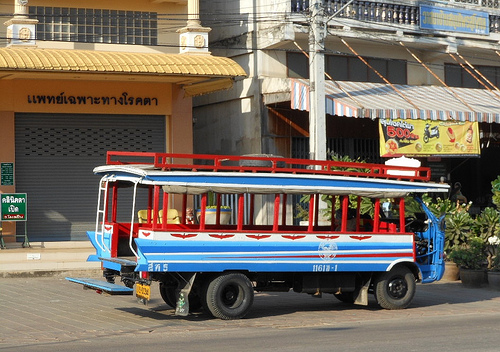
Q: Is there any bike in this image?
A: No, there are no bikes.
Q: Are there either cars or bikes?
A: No, there are no bikes or cars.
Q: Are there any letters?
A: Yes, there are letters.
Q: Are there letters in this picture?
A: Yes, there are letters.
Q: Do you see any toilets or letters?
A: Yes, there are letters.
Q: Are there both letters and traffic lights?
A: No, there are letters but no traffic lights.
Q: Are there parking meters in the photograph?
A: No, there are no parking meters.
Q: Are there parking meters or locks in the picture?
A: No, there are no parking meters or locks.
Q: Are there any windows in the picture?
A: Yes, there is a window.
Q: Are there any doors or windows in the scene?
A: Yes, there is a window.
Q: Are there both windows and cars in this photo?
A: No, there is a window but no cars.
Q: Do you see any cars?
A: No, there are no cars.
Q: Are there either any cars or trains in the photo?
A: No, there are no cars or trains.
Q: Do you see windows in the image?
A: Yes, there is a window.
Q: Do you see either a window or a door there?
A: Yes, there is a window.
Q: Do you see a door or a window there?
A: Yes, there is a window.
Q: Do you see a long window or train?
A: Yes, there is a long window.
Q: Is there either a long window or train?
A: Yes, there is a long window.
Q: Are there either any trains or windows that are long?
A: Yes, the window is long.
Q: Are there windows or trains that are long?
A: Yes, the window is long.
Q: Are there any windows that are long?
A: Yes, there is a long window.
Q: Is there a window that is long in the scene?
A: Yes, there is a long window.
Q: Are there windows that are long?
A: Yes, there is a window that is long.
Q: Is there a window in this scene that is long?
A: Yes, there is a window that is long.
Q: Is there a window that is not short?
A: Yes, there is a long window.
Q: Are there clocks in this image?
A: No, there are no clocks.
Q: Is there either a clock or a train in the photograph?
A: No, there are no clocks or trains.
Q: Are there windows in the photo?
A: Yes, there is a window.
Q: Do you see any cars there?
A: No, there are no cars.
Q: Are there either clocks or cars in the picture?
A: No, there are no cars or clocks.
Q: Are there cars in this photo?
A: No, there are no cars.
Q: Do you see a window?
A: Yes, there is a window.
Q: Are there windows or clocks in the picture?
A: Yes, there is a window.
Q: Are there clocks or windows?
A: Yes, there is a window.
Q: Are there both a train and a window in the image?
A: No, there is a window but no trains.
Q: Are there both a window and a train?
A: No, there is a window but no trains.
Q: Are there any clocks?
A: No, there are no clocks.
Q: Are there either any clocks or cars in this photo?
A: No, there are no clocks or cars.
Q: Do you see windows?
A: Yes, there is a window.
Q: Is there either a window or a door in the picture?
A: Yes, there is a window.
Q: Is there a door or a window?
A: Yes, there is a window.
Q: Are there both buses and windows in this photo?
A: Yes, there are both a window and a bus.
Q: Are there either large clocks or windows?
A: Yes, there is a large window.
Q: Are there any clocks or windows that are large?
A: Yes, the window is large.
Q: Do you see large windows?
A: Yes, there is a large window.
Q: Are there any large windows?
A: Yes, there is a large window.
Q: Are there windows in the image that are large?
A: Yes, there is a window that is large.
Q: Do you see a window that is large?
A: Yes, there is a window that is large.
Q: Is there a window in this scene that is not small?
A: Yes, there is a large window.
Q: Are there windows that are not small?
A: Yes, there is a large window.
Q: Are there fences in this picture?
A: No, there are no fences.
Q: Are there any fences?
A: No, there are no fences.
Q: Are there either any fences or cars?
A: No, there are no fences or cars.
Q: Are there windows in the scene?
A: Yes, there is a window.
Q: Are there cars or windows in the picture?
A: Yes, there is a window.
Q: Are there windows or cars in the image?
A: Yes, there is a window.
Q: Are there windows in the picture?
A: Yes, there is a window.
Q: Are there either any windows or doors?
A: Yes, there is a window.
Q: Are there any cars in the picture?
A: No, there are no cars.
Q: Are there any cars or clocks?
A: No, there are no cars or clocks.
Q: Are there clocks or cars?
A: No, there are no cars or clocks.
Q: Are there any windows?
A: Yes, there is a window.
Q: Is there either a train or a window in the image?
A: Yes, there is a window.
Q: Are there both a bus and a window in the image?
A: Yes, there are both a window and a bus.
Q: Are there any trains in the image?
A: No, there are no trains.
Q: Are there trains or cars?
A: No, there are no trains or cars.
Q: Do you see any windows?
A: Yes, there is a window.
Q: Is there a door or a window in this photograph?
A: Yes, there is a window.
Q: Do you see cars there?
A: No, there are no cars.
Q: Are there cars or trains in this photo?
A: No, there are no cars or trains.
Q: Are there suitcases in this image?
A: No, there are no suitcases.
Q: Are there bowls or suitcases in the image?
A: No, there are no suitcases or bowls.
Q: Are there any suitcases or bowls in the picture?
A: No, there are no suitcases or bowls.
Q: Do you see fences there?
A: No, there are no fences.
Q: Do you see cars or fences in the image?
A: No, there are no fences or cars.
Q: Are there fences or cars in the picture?
A: No, there are no fences or cars.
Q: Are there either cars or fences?
A: No, there are no fences or cars.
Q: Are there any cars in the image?
A: No, there are no cars.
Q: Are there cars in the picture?
A: No, there are no cars.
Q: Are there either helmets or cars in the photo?
A: No, there are no cars or helmets.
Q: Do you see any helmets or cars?
A: No, there are no cars or helmets.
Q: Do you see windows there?
A: Yes, there is a window.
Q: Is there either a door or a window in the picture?
A: Yes, there is a window.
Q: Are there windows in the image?
A: Yes, there is a window.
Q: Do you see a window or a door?
A: Yes, there is a window.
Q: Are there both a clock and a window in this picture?
A: No, there is a window but no clocks.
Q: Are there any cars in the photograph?
A: No, there are no cars.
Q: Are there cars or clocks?
A: No, there are no cars or clocks.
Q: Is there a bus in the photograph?
A: Yes, there is a bus.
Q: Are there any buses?
A: Yes, there is a bus.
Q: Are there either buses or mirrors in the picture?
A: Yes, there is a bus.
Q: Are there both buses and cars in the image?
A: No, there is a bus but no cars.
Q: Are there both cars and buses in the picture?
A: No, there is a bus but no cars.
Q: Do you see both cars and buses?
A: No, there is a bus but no cars.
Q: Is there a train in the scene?
A: No, there are no trains.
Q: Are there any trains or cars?
A: No, there are no trains or cars.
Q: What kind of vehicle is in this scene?
A: The vehicle is a bus.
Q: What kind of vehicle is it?
A: The vehicle is a bus.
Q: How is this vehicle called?
A: This is a bus.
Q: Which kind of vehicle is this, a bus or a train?
A: This is a bus.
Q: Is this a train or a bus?
A: This is a bus.